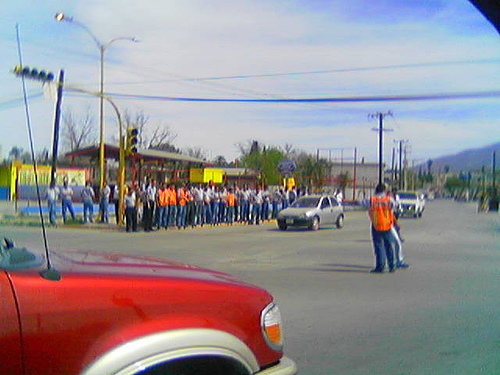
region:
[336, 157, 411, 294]
the man with orange vest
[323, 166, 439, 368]
the man with orange vest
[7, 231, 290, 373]
red suv driving on street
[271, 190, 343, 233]
silver subcompact car on street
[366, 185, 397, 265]
man in orange construction vest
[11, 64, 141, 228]
yellow streetlight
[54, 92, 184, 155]
trees with no leaves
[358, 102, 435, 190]
wood powerlines in distance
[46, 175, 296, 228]
people standing along the street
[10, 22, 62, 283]
black car attenna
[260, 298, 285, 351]
white and orange headlight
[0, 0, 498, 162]
blue and white sky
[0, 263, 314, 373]
red vehicle in street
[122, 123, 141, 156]
black and yellow traffic signal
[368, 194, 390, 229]
orange safety vest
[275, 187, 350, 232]
silver car driving on street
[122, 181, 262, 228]
row of people standing beside street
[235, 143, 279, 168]
trees with green leaves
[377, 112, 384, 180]
brown electric line pole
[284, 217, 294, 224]
license plate on front of car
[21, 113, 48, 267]
black car radio antenna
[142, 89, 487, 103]
power lines hanging over street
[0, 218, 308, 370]
a red truck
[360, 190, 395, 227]
an orange vest on a man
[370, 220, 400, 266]
a man in blue jeans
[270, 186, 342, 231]
a gray car on a road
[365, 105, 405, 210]
a utility pole along a road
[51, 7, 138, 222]
a double headed light pole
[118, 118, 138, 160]
a stoplight on the side of the road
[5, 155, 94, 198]
a yellow wall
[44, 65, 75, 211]
a tall wooden post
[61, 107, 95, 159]
a bare leafless tree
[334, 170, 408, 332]
the guy in orange vest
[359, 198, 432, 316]
the guy in orange vest